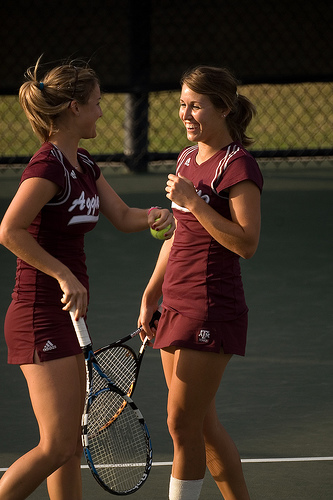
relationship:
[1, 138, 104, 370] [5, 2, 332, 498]
outfit for tennis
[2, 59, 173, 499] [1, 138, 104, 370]
woman wears an outfit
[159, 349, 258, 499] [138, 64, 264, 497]
legs of player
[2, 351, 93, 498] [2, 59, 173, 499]
legs of woman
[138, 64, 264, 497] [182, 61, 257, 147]
player has brown hair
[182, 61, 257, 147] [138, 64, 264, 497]
brown hair on a player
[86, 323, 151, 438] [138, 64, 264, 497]
racquet of player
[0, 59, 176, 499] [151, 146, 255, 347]
woman wearing marroon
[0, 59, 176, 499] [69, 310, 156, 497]
woman have racquets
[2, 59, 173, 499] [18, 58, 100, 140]
woman has blond hair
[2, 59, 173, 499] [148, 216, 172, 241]
woman holds ball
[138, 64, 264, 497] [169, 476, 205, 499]
player wears a sock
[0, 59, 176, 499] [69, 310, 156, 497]
woman both have racquets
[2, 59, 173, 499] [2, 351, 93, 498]
woman shows legs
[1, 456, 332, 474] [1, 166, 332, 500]
line on court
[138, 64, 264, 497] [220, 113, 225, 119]
player wears a earring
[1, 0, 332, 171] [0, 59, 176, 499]
fence behind woman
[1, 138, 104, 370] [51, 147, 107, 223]
jersey has white print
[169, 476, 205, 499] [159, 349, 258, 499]
tape on leg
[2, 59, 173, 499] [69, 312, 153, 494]
woman holds a racquet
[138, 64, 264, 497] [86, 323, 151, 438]
player holds a racquet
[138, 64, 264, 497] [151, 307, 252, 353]
player wears a skirt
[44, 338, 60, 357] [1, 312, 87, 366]
logo on skirt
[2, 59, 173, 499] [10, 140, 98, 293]
woman wears a marroon jersey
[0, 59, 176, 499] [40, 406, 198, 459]
woman show their knees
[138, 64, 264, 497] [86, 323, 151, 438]
player shows a partial racquet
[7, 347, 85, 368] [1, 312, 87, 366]
hem of skirt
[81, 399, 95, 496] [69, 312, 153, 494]
edge of a racquet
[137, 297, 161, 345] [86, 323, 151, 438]
hand holding racquet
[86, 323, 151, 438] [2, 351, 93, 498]
racquet behind womans legs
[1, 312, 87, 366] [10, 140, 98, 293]
skirt under jersey